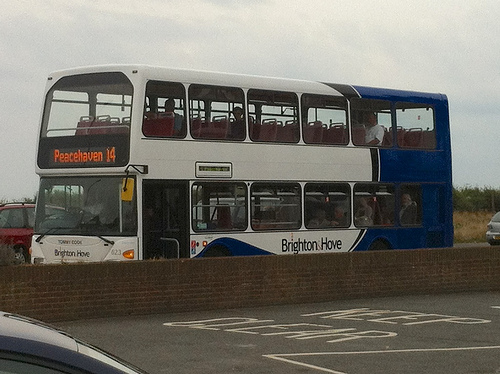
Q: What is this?
A: A bus.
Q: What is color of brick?
A: Red.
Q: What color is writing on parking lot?
A: White.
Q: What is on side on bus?
A: Windows.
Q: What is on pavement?
A: Writing.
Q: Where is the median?
A: In the road.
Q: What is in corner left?
A: Hood of car.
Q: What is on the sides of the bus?
A: Windows.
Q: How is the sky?
A: Overcast.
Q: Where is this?
A: Busy street.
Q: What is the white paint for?
A: Information.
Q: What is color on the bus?
A: Blue.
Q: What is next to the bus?
A: Car.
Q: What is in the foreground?
A: Street.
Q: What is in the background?
A: Trees.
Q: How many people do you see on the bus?
A: 7.